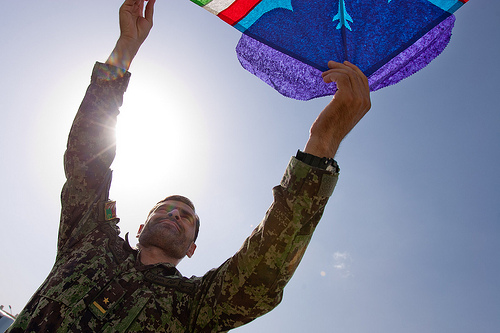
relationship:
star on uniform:
[102, 297, 108, 304] [7, 60, 337, 327]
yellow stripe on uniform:
[75, 272, 150, 331] [7, 60, 337, 327]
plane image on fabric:
[332, 1, 354, 31] [192, 0, 471, 101]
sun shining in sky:
[44, 74, 189, 194] [1, 2, 493, 329]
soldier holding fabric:
[9, 5, 381, 330] [188, 0, 472, 101]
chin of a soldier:
[147, 229, 174, 247] [9, 5, 381, 330]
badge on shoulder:
[103, 199, 121, 226] [80, 226, 137, 261]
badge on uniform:
[103, 199, 121, 226] [7, 60, 337, 327]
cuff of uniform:
[278, 156, 339, 200] [7, 60, 337, 327]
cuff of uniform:
[86, 57, 132, 91] [7, 60, 337, 327]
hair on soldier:
[147, 187, 209, 242] [9, 5, 381, 330]